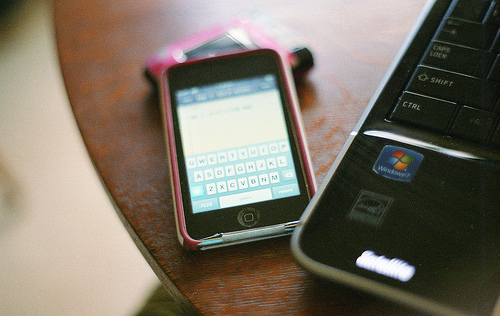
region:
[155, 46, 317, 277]
cellphone on a desk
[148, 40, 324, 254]
red cellphone on a desk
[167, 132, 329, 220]
keyboard on a red cell phone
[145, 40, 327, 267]
cellphone with a red cover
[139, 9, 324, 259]
two red cellphones on a wooden surface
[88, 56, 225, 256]
wooden table with a cellphone on top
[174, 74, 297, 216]
cellphone interface when turned on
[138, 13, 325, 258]
flip phone behind a smartphone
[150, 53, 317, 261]
red smartphone with the keyboard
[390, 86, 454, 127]
control button on ana electronic device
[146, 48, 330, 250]
old iphone on table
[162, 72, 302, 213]
iphone screen of phone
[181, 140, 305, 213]
iphone keyboard of phone laying on table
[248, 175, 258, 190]
the letter of keyboard of phone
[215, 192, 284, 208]
space bar of key board of phone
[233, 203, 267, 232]
home button of iphone on table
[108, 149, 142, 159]
brown part of table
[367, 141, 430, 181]
windows sticker on laptop computer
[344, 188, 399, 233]
energy star sticker on laptop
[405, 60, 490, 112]
shift key on laptop keyboard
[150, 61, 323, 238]
cellphone sitting on table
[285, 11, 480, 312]
side of laptop on table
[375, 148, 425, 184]
windows symbol on laptop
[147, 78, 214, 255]
pink case of cellphone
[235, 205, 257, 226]
round button on phone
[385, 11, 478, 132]
black keys on keyboard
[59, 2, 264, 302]
wood surface of table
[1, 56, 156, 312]
white floor below table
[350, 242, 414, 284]
illuminated logo of laptop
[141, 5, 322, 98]
second phone under first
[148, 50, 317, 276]
a phone on the table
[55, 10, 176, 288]
a brown wooden table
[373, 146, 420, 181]
windows sticker on phone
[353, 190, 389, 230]
intel sticker on phone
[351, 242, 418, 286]
white writing on phone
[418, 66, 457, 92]
shift key on keyboard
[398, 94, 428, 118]
ctrl button on keyboard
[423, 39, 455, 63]
capslock button on keyboard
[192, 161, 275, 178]
keyboard on cellphone screen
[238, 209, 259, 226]
power button on phone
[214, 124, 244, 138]
white screen on phone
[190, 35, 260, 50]
pink cellphone behind phone